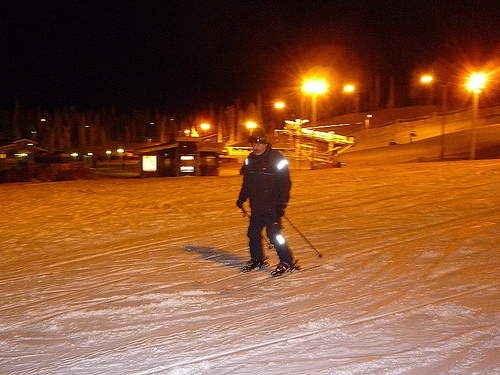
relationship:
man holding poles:
[228, 128, 301, 278] [229, 204, 331, 262]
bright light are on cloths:
[276, 235, 286, 244] [239, 155, 296, 261]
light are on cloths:
[276, 158, 289, 170] [239, 155, 296, 261]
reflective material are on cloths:
[244, 158, 248, 166] [239, 155, 296, 261]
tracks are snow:
[135, 282, 496, 373] [12, 199, 482, 372]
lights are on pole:
[301, 73, 331, 97] [310, 95, 320, 167]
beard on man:
[249, 142, 268, 159] [223, 116, 330, 280]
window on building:
[15, 149, 33, 159] [1, 133, 63, 184]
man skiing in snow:
[236, 126, 299, 277] [5, 272, 497, 372]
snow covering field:
[0, 159, 499, 374] [0, 157, 500, 374]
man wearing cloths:
[236, 126, 299, 277] [237, 142, 292, 262]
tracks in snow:
[7, 220, 246, 256] [0, 159, 499, 374]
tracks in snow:
[135, 282, 496, 373] [0, 159, 499, 374]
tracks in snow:
[323, 175, 497, 235] [0, 159, 499, 374]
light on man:
[264, 159, 305, 181] [184, 121, 392, 283]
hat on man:
[246, 135, 273, 144] [232, 130, 296, 281]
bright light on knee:
[275, 233, 286, 245] [267, 232, 279, 245]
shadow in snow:
[177, 223, 264, 278] [0, 173, 245, 367]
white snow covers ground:
[231, 326, 338, 371] [0, 234, 497, 374]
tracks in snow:
[0, 220, 247, 282] [0, 159, 499, 374]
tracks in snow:
[288, 178, 397, 210] [0, 159, 499, 374]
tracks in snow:
[359, 235, 463, 310] [0, 159, 499, 374]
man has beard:
[236, 126, 299, 277] [250, 148, 266, 156]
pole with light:
[462, 96, 484, 161] [458, 62, 490, 95]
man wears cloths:
[236, 126, 299, 277] [237, 142, 292, 262]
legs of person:
[239, 211, 291, 279] [213, 116, 313, 296]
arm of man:
[236, 175, 247, 210] [236, 126, 299, 277]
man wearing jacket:
[236, 126, 299, 277] [239, 151, 295, 213]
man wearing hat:
[236, 126, 299, 277] [234, 118, 283, 158]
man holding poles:
[236, 126, 299, 277] [282, 212, 325, 260]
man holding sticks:
[236, 126, 299, 277] [226, 190, 281, 267]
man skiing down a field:
[236, 126, 299, 277] [0, 157, 500, 374]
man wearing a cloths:
[236, 126, 299, 277] [237, 142, 292, 262]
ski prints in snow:
[0, 232, 499, 372] [0, 108, 497, 373]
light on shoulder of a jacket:
[276, 158, 289, 170] [238, 150, 293, 208]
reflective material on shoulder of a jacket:
[242, 154, 249, 165] [238, 150, 293, 208]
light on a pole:
[462, 66, 493, 93] [469, 94, 483, 162]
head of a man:
[250, 141, 268, 155] [236, 126, 299, 277]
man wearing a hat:
[236, 126, 299, 277] [249, 127, 268, 140]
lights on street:
[301, 76, 331, 98] [214, 131, 496, 170]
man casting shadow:
[236, 126, 299, 277] [175, 239, 267, 271]